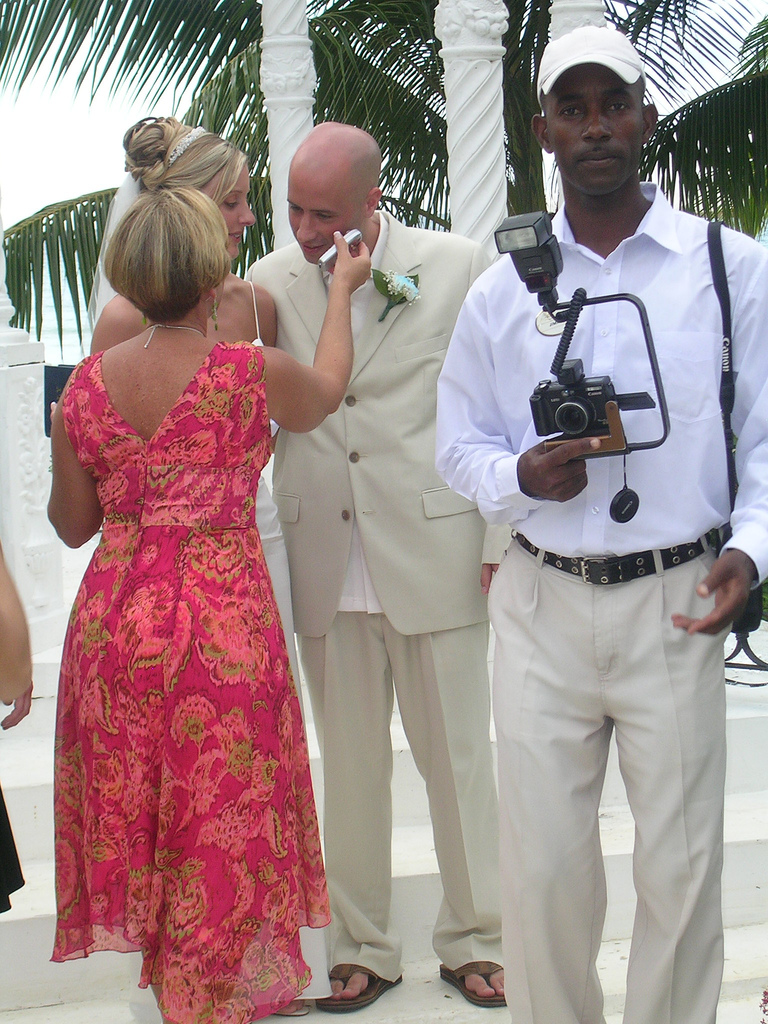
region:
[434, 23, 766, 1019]
the man holding the camera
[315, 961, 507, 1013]
the slippers are brown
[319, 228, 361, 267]
the cellphone is silver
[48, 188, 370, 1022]
the woman wearing the pink dress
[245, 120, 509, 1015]
the man wearing the suit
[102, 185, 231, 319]
the hair is blonde and short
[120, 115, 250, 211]
the hair is blond and in an updo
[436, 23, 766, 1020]
the man wearing the white hat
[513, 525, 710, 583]
the belt is black with silver holes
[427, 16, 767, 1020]
man is holding a camera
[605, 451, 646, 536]
lens cap is hanging down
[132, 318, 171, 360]
chain from the necklace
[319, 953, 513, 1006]
a pair of sandals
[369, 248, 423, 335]
white flower is on the jacket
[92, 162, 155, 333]
white veil is hanging down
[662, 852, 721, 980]
wrinkle in the pant leg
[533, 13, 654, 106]
white hat is on the head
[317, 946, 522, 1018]
Man wearing sandals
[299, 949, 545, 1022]
Man is wearing sandals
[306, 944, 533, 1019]
Man wearing brown sandals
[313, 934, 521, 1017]
Man is wearing brown sandals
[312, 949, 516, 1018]
Man is wearing flip flops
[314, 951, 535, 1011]
Man wearing brown flip flops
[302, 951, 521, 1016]
Man is wearing brown flip flops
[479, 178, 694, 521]
Man holding a camera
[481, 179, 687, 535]
Man is holding a camera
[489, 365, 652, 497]
the man is holding the camera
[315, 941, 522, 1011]
the man is wearing sandles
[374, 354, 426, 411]
the jacket is cream in color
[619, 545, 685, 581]
the belt is black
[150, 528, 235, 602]
the dress is colorful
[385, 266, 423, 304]
the flower is blue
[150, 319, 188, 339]
she is wearing a necklace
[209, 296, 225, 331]
the earring is green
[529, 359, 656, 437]
a black camera with a silver focus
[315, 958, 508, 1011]
a pair of brown leather sandals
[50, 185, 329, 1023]
blonde woman wearing a pink floral dress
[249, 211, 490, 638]
a white boutonniere pinned on a white jacket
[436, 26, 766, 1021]
man with white cap holding a camera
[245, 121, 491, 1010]
a balding man wearing a white suit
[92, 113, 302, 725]
a blond woman wearing a white veil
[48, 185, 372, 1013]
blonde woman holding a silver cellphone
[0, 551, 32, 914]
a woman wearing a black dress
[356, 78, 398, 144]
green leaves on the tree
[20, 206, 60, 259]
green leaves on the tree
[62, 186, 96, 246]
green leaves on the tree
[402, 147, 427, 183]
green leaves on the tree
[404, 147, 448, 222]
green leaves on the tree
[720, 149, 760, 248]
green leaves on the tree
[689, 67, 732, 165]
green leaves on the tree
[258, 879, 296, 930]
pattern on pink dress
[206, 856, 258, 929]
pattern on pink dress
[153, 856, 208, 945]
pattern on pink dress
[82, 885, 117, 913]
pattern on pink dress